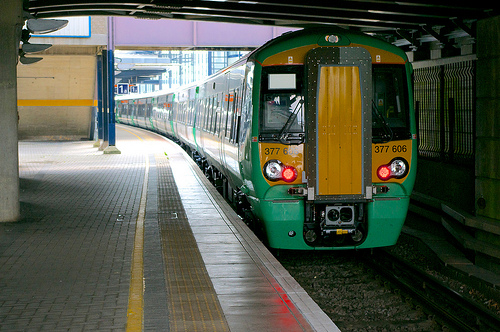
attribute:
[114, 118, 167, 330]
stripe — yellow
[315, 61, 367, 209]
door — yellow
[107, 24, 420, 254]
train — yellow, green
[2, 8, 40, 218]
pillar — cement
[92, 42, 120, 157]
support column — metal, blue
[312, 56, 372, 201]
door — yellow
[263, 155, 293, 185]
light — red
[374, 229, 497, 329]
track — steel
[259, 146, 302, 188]
light — red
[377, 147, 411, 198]
light — red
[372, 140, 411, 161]
numbers — black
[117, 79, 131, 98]
sign — white, blue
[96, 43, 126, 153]
support post — blue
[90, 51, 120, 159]
poles — blue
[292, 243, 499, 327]
rails — soil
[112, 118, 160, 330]
line — yellow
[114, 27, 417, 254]
subway train — yellow and pale green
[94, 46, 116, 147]
poles — blue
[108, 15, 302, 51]
overpass — purple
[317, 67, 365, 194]
door — yellow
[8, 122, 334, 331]
zone — passenger loading and unloading zone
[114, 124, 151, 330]
line — yellow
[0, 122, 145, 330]
walkway — brick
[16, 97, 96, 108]
line — yellow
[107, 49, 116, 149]
pole — blue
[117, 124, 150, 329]
line — yellow, painted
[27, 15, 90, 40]
sign — white and blue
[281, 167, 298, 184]
light — red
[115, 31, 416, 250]
light — red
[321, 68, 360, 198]
door — yellow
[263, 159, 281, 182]
light — black and silver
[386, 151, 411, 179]
light — silver, black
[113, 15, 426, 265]
train — green, yellow, black